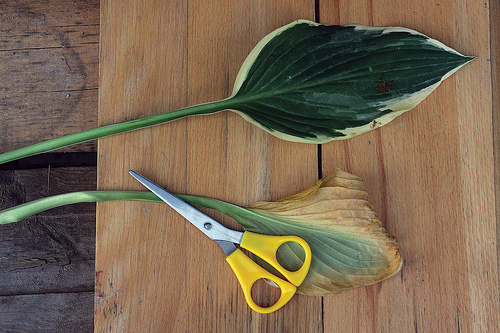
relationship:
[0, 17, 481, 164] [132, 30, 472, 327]
leaf in table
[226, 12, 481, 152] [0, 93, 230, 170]
leaf in stem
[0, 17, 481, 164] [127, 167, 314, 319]
leaf in scissors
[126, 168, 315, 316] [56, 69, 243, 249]
scissors on table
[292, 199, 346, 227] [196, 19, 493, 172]
brown spot on leaf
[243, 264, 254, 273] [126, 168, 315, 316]
part of scissors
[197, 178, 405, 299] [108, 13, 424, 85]
leaf laying on table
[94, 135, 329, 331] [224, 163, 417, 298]
scissors laying on leaf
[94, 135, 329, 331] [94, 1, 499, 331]
scissors laying on wood